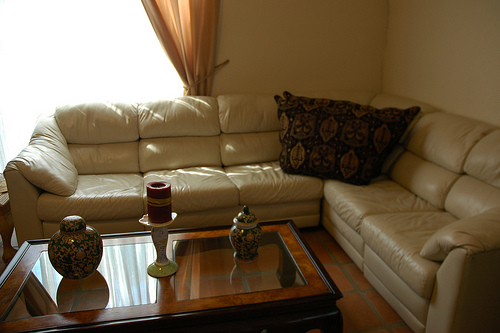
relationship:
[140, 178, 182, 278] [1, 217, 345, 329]
candle on coffee table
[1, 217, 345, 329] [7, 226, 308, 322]
coffee table has top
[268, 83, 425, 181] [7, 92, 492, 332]
cushion on couch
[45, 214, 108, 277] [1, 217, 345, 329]
decorations on coffee table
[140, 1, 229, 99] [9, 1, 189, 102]
curtain pulled back from window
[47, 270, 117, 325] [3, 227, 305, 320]
reflection on glass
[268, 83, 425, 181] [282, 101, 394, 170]
cushion with pattern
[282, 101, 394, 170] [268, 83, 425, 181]
pattern on cushion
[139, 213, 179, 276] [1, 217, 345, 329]
candelabra on coffee table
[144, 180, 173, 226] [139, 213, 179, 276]
candle on candelabra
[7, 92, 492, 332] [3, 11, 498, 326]
couch in living room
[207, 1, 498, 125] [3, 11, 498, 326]
walls in living room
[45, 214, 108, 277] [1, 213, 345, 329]
decorations on coffee table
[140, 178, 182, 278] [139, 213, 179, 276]
candle on candelabra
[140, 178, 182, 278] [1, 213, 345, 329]
candle on coffee table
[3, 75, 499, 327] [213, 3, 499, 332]
sectional in corner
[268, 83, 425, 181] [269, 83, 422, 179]
cushion in corner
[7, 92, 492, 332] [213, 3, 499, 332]
couch has corner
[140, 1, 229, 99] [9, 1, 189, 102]
curtain on window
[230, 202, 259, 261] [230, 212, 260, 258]
pot with design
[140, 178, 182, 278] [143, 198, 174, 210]
candle with design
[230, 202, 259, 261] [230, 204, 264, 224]
pot with lid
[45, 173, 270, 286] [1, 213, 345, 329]
decorations on coffee table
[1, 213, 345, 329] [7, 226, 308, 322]
coffee table with top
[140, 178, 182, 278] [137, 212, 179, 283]
candle in candelabra